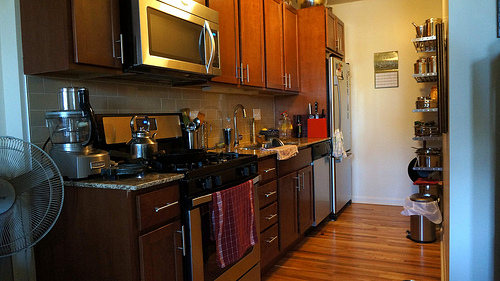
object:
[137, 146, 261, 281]
oven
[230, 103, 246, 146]
faucet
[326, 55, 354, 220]
refrigerator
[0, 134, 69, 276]
fan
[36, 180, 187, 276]
cabinet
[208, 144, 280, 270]
cabinet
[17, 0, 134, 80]
cabinet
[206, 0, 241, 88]
cabinet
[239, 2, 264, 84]
door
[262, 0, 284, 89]
door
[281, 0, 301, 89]
door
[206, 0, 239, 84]
door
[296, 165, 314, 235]
door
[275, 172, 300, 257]
door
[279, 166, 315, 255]
cabinet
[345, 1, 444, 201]
wall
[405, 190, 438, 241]
trash bin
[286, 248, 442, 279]
panels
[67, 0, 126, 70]
door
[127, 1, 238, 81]
microwave oven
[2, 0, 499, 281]
kitchen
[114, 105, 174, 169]
kettle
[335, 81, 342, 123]
refrigerator handle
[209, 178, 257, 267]
dish towel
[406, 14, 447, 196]
pantry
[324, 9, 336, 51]
door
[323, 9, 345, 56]
cabinet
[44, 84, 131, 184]
processor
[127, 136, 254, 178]
stovetop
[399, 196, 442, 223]
bag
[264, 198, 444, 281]
floor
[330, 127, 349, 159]
towel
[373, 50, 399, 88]
calendar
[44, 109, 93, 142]
bowl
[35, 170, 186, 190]
countertop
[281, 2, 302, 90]
cabinet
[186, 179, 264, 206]
oven handle